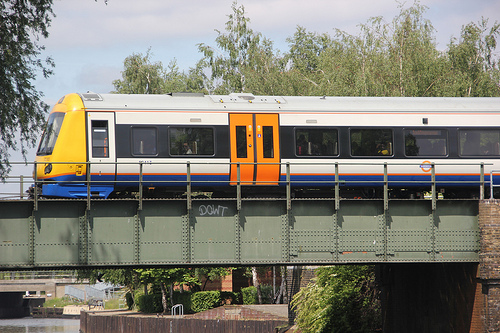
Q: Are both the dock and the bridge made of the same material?
A: No, the dock is made of concrete and the bridge is made of metal.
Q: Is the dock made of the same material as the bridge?
A: No, the dock is made of concrete and the bridge is made of metal.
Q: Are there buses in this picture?
A: No, there are no buses.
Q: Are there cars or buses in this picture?
A: No, there are no buses or cars.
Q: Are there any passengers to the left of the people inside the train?
A: Yes, there is a passenger to the left of the people.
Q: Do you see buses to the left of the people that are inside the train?
A: No, there is a passenger to the left of the people.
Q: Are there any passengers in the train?
A: Yes, there is a passenger in the train.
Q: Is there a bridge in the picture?
A: Yes, there is a bridge.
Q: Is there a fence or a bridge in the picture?
A: Yes, there is a bridge.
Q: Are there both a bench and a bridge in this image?
A: No, there is a bridge but no benches.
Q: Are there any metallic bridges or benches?
A: Yes, there is a metal bridge.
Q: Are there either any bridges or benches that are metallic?
A: Yes, the bridge is metallic.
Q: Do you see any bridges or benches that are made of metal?
A: Yes, the bridge is made of metal.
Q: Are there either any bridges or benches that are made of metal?
A: Yes, the bridge is made of metal.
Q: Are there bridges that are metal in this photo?
A: Yes, there is a metal bridge.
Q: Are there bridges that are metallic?
A: Yes, there is a bridge that is metallic.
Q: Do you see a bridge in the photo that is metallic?
A: Yes, there is a bridge that is metallic.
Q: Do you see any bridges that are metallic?
A: Yes, there is a bridge that is metallic.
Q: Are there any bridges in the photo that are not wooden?
A: Yes, there is a metallic bridge.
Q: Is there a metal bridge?
A: Yes, there is a bridge that is made of metal.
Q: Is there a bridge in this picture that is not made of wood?
A: Yes, there is a bridge that is made of metal.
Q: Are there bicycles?
A: No, there are no bicycles.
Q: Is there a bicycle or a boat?
A: No, there are no bicycles or boats.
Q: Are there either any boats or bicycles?
A: No, there are no bicycles or boats.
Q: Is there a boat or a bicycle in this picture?
A: No, there are no bicycles or boats.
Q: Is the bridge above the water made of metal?
A: Yes, the bridge is made of metal.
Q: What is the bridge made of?
A: The bridge is made of metal.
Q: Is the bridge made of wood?
A: No, the bridge is made of metal.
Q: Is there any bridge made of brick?
A: No, there is a bridge but it is made of metal.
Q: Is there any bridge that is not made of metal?
A: No, there is a bridge but it is made of metal.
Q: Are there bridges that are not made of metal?
A: No, there is a bridge but it is made of metal.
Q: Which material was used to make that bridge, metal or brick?
A: The bridge is made of metal.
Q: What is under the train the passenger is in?
A: The bridge is under the train.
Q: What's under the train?
A: The bridge is under the train.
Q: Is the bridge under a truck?
A: No, the bridge is under the train.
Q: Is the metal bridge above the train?
A: No, the bridge is under the train.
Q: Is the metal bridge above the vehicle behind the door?
A: No, the bridge is under the train.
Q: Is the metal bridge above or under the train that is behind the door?
A: The bridge is under the train.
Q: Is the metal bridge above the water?
A: Yes, the bridge is above the water.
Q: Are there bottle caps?
A: No, there are no bottle caps.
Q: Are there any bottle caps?
A: No, there are no bottle caps.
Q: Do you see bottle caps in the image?
A: No, there are no bottle caps.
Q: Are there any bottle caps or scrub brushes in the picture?
A: No, there are no bottle caps or scrub brushes.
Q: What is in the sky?
A: The clouds are in the sky.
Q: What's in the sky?
A: The clouds are in the sky.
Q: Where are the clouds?
A: The clouds are in the sky.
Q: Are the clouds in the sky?
A: Yes, the clouds are in the sky.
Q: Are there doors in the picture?
A: Yes, there is a door.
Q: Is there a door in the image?
A: Yes, there is a door.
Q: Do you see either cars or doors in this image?
A: Yes, there is a door.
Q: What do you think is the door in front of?
A: The door is in front of the train.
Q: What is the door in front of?
A: The door is in front of the train.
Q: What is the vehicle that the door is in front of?
A: The vehicle is a train.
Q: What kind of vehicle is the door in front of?
A: The door is in front of the train.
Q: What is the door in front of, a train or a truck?
A: The door is in front of a train.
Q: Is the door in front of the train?
A: Yes, the door is in front of the train.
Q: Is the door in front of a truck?
A: No, the door is in front of the train.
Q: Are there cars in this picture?
A: No, there are no cars.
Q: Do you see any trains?
A: Yes, there is a train.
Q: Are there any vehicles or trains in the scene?
A: Yes, there is a train.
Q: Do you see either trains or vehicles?
A: Yes, there is a train.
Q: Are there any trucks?
A: No, there are no trucks.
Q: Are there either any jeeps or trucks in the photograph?
A: No, there are no trucks or jeeps.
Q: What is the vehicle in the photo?
A: The vehicle is a train.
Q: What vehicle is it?
A: The vehicle is a train.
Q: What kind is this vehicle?
A: This is a train.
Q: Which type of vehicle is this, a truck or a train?
A: This is a train.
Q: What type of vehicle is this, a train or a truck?
A: This is a train.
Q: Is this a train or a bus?
A: This is a train.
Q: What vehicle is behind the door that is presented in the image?
A: The vehicle is a train.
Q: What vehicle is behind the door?
A: The vehicle is a train.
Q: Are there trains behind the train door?
A: Yes, there is a train behind the door.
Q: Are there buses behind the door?
A: No, there is a train behind the door.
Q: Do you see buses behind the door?
A: No, there is a train behind the door.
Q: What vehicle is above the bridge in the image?
A: The vehicle is a train.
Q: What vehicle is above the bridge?
A: The vehicle is a train.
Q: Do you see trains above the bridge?
A: Yes, there is a train above the bridge.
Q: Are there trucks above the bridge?
A: No, there is a train above the bridge.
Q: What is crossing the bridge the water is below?
A: The train is crossing the bridge.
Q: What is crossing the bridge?
A: The train is crossing the bridge.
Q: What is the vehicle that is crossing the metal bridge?
A: The vehicle is a train.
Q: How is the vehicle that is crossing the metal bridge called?
A: The vehicle is a train.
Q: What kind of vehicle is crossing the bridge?
A: The vehicle is a train.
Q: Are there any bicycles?
A: No, there are no bicycles.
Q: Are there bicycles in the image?
A: No, there are no bicycles.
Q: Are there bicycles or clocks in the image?
A: No, there are no bicycles or clocks.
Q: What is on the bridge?
A: The graffiti is on the bridge.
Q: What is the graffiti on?
A: The graffiti is on the bridge.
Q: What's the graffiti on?
A: The graffiti is on the bridge.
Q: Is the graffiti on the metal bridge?
A: Yes, the graffiti is on the bridge.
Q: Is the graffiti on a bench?
A: No, the graffiti is on the bridge.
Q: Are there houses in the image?
A: No, there are no houses.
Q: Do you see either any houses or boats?
A: No, there are no houses or boats.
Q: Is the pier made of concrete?
A: Yes, the pier is made of concrete.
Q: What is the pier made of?
A: The pier is made of concrete.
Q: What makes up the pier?
A: The pier is made of concrete.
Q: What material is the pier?
A: The pier is made of concrete.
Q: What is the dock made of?
A: The pier is made of concrete.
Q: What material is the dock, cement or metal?
A: The dock is made of cement.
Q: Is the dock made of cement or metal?
A: The dock is made of cement.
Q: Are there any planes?
A: No, there are no planes.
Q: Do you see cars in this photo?
A: No, there are no cars.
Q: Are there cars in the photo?
A: No, there are no cars.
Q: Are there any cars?
A: No, there are no cars.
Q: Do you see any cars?
A: No, there are no cars.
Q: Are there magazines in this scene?
A: No, there are no magazines.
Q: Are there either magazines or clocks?
A: No, there are no magazines or clocks.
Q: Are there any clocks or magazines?
A: No, there are no magazines or clocks.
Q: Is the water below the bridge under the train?
A: Yes, the water is below the bridge.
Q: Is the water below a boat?
A: No, the water is below the bridge.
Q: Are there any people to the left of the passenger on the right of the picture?
A: Yes, there are people to the left of the passenger.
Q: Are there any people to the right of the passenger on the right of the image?
A: No, the people are to the left of the passenger.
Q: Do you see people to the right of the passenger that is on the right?
A: No, the people are to the left of the passenger.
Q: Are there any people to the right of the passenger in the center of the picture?
A: Yes, there are people to the right of the passenger.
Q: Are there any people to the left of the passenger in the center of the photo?
A: No, the people are to the right of the passenger.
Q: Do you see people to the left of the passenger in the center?
A: No, the people are to the right of the passenger.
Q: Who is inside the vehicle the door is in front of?
A: The people are inside the train.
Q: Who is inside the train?
A: The people are inside the train.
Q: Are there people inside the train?
A: Yes, there are people inside the train.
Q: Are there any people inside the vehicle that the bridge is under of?
A: Yes, there are people inside the train.